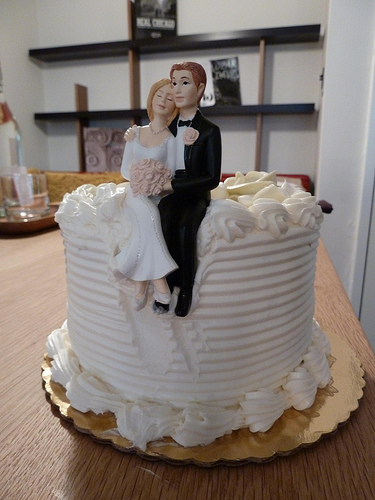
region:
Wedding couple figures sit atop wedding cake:
[114, 61, 230, 318]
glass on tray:
[13, 169, 51, 224]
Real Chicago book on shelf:
[130, 0, 179, 40]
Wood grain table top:
[3, 388, 41, 494]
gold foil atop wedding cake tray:
[332, 340, 347, 414]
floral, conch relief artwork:
[84, 125, 119, 174]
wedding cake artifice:
[109, 277, 224, 390]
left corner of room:
[30, 64, 55, 108]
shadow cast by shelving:
[267, 116, 315, 141]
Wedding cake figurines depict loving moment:
[145, 60, 209, 126]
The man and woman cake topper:
[100, 52, 223, 319]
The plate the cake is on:
[38, 321, 367, 466]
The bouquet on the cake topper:
[126, 158, 174, 196]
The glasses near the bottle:
[0, 169, 50, 223]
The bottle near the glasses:
[0, 72, 24, 212]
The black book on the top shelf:
[131, 0, 180, 39]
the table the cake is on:
[0, 204, 374, 496]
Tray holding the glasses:
[0, 201, 62, 235]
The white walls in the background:
[0, 0, 374, 351]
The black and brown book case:
[23, 2, 324, 170]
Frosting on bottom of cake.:
[118, 369, 311, 445]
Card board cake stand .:
[186, 361, 364, 477]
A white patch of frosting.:
[213, 245, 311, 375]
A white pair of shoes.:
[114, 287, 171, 319]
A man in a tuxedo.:
[159, 59, 220, 305]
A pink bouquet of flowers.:
[118, 155, 180, 198]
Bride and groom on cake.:
[90, 55, 207, 322]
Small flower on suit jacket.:
[172, 124, 200, 150]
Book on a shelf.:
[209, 50, 250, 127]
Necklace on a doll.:
[133, 116, 174, 144]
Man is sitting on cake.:
[158, 61, 219, 316]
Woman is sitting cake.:
[116, 60, 176, 315]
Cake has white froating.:
[39, 174, 341, 453]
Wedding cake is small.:
[36, 52, 338, 452]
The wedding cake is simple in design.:
[34, 58, 346, 452]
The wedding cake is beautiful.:
[39, 60, 340, 451]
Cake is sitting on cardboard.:
[19, 317, 369, 465]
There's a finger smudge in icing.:
[117, 395, 166, 456]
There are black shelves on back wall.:
[9, 19, 320, 188]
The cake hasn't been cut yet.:
[40, 60, 334, 456]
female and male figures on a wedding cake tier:
[117, 47, 219, 315]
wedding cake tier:
[52, 171, 326, 443]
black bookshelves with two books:
[25, 3, 330, 115]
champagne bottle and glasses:
[1, 64, 55, 236]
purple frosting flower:
[315, 193, 338, 219]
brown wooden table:
[4, 243, 43, 410]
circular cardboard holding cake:
[326, 329, 365, 445]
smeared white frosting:
[117, 309, 195, 459]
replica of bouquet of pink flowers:
[129, 156, 171, 201]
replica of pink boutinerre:
[180, 126, 201, 151]